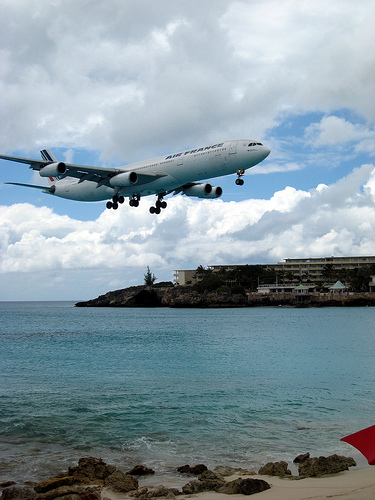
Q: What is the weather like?
A: It is clear.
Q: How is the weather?
A: It is clear.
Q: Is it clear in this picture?
A: Yes, it is clear.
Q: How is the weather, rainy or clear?
A: It is clear.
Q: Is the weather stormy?
A: No, it is clear.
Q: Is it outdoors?
A: Yes, it is outdoors.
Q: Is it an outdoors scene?
A: Yes, it is outdoors.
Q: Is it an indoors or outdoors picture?
A: It is outdoors.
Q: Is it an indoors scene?
A: No, it is outdoors.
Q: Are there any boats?
A: No, there are no boats.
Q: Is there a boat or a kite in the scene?
A: No, there are no boats or kites.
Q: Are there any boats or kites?
A: No, there are no boats or kites.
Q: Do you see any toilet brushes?
A: No, there are no toilet brushes.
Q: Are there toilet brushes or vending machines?
A: No, there are no toilet brushes or vending machines.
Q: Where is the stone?
A: The stone is on the beach.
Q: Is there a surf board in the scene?
A: No, there are no surfboards.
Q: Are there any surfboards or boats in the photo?
A: No, there are no surfboards or boats.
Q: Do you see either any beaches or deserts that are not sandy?
A: No, there is a beach but it is sandy.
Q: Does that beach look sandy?
A: Yes, the beach is sandy.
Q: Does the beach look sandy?
A: Yes, the beach is sandy.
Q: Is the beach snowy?
A: No, the beach is sandy.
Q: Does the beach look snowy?
A: No, the beach is sandy.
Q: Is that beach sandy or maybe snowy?
A: The beach is sandy.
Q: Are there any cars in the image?
A: No, there are no cars.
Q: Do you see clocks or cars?
A: No, there are no cars or clocks.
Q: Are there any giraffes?
A: No, there are no giraffes.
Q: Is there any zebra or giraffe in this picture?
A: No, there are no giraffes or zebras.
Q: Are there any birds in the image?
A: No, there are no birds.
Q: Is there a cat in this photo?
A: No, there are no cats.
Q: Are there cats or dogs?
A: No, there are no cats or dogs.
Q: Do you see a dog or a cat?
A: No, there are no cats or dogs.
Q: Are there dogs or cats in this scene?
A: No, there are no cats or dogs.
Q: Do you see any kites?
A: No, there are no kites.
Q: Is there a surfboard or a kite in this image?
A: No, there are no kites or surfboards.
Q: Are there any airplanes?
A: Yes, there is an airplane.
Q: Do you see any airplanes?
A: Yes, there is an airplane.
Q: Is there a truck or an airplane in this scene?
A: Yes, there is an airplane.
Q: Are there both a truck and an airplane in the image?
A: No, there is an airplane but no trucks.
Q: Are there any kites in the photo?
A: No, there are no kites.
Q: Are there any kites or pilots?
A: No, there are no kites or pilots.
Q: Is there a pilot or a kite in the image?
A: No, there are no kites or pilots.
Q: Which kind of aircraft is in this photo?
A: The aircraft is an airplane.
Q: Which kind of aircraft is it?
A: The aircraft is an airplane.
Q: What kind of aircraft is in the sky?
A: The aircraft is an airplane.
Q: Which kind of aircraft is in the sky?
A: The aircraft is an airplane.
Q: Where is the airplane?
A: The airplane is in the sky.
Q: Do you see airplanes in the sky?
A: Yes, there is an airplane in the sky.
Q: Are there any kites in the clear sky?
A: No, there is an airplane in the sky.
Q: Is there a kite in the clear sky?
A: No, there is an airplane in the sky.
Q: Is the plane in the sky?
A: Yes, the plane is in the sky.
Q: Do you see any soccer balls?
A: No, there are no soccer balls.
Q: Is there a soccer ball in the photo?
A: No, there are no soccer balls.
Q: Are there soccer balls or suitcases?
A: No, there are no soccer balls or suitcases.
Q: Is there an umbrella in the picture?
A: Yes, there is an umbrella.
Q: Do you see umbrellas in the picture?
A: Yes, there is an umbrella.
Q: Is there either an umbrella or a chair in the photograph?
A: Yes, there is an umbrella.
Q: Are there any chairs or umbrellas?
A: Yes, there is an umbrella.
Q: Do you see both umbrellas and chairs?
A: No, there is an umbrella but no chairs.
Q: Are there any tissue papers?
A: No, there are no tissue papers.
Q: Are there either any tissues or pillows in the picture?
A: No, there are no tissues or pillows.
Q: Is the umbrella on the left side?
A: No, the umbrella is on the right of the image.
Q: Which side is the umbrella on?
A: The umbrella is on the right of the image.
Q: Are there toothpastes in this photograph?
A: No, there are no toothpastes.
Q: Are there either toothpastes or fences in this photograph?
A: No, there are no toothpastes or fences.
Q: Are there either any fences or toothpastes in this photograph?
A: No, there are no toothpastes or fences.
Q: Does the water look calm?
A: Yes, the water is calm.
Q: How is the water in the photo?
A: The water is calm.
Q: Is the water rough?
A: No, the water is calm.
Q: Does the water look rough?
A: No, the water is calm.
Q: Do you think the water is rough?
A: No, the water is calm.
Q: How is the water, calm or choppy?
A: The water is calm.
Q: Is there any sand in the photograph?
A: Yes, there is sand.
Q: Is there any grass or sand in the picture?
A: Yes, there is sand.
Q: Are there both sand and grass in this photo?
A: No, there is sand but no grass.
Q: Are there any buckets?
A: No, there are no buckets.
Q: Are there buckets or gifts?
A: No, there are no buckets or gifts.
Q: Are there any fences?
A: No, there are no fences.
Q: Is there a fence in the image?
A: No, there are no fences.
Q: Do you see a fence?
A: No, there are no fences.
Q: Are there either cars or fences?
A: No, there are no fences or cars.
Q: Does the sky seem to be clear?
A: Yes, the sky is clear.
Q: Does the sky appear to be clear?
A: Yes, the sky is clear.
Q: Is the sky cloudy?
A: No, the sky is clear.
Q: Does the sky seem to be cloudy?
A: No, the sky is clear.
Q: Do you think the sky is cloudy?
A: No, the sky is clear.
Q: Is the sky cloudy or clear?
A: The sky is clear.